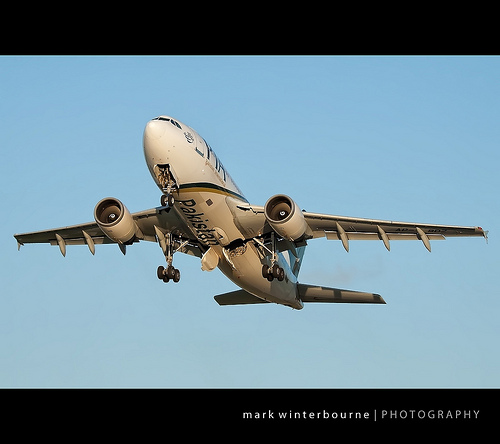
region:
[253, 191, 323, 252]
a jet engine on a wing.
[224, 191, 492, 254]
a jet engine on a wing.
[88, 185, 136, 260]
a jet engine.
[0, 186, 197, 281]
a wing with a jet engine.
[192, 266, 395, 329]
a tail wing on a jet.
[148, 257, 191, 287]
landing gear on a jet.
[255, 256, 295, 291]
landing gear.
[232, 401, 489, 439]
a water mark on a picture.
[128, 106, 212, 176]
a cock pit on a jet.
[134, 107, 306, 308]
a center of a jetliner.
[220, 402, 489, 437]
photo info on bottom right corner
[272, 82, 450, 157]
part of the sky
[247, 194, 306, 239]
part of airplane's engine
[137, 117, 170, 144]
nose of the airpane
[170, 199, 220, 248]
name of airplane carrier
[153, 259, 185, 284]
wheels on the airplane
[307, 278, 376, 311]
part of the airplane's tail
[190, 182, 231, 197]
gold and blue stripes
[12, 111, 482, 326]
picture of an airplane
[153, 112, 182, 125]
front window on airplane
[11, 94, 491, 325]
a plane ina blue sky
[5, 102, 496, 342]
plane is color tan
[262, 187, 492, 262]
right wing of a plane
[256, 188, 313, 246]
engine in front of right wing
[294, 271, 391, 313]
horizontal stabilizer on right side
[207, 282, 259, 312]
horizontal stabilizer on left side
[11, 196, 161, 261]
left wing of plane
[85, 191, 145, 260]
engine in front of left wing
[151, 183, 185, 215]
black wheels in front of plane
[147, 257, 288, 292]
black wheels of plane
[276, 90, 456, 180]
the sky is skyblue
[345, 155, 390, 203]
the sky is skyblue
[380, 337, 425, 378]
the sky is skyblue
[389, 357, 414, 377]
the sky is skyblue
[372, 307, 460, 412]
the sky is skyblue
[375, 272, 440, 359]
the sky is skyblue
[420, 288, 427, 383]
the sky is skybluethe sky is skyblue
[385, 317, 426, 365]
the sky is skyblue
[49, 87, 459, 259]
the plane is lifting up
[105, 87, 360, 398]
the plane is lifting up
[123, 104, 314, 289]
the plane is lifting up